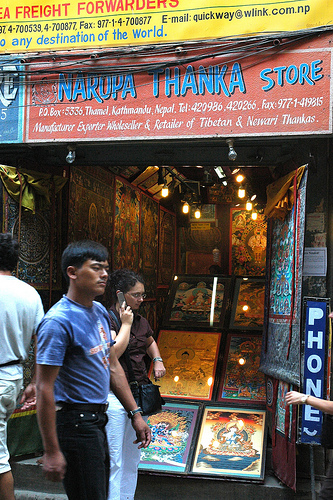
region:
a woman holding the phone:
[99, 268, 165, 392]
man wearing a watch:
[120, 399, 167, 447]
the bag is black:
[124, 370, 182, 431]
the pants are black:
[41, 390, 136, 497]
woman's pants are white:
[91, 386, 159, 496]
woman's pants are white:
[105, 382, 137, 496]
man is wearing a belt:
[75, 383, 104, 428]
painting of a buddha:
[197, 394, 275, 480]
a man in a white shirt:
[0, 233, 35, 499]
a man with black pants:
[43, 243, 113, 499]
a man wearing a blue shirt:
[42, 244, 111, 498]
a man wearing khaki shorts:
[0, 242, 39, 498]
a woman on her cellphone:
[110, 270, 147, 317]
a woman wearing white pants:
[110, 273, 144, 498]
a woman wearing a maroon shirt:
[111, 272, 159, 499]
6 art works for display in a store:
[161, 272, 270, 483]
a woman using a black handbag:
[111, 273, 162, 411]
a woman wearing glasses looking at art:
[112, 266, 148, 310]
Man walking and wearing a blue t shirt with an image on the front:
[23, 230, 125, 497]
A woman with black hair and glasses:
[110, 267, 169, 376]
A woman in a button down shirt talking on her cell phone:
[110, 275, 150, 356]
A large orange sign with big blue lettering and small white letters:
[26, 63, 329, 136]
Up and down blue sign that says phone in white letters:
[285, 285, 326, 462]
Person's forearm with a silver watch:
[282, 385, 330, 419]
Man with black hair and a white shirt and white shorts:
[0, 226, 29, 478]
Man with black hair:
[53, 232, 113, 310]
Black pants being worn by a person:
[29, 389, 119, 498]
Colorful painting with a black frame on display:
[190, 396, 272, 497]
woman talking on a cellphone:
[112, 261, 164, 377]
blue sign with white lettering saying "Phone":
[296, 297, 325, 453]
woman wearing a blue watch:
[152, 356, 164, 362]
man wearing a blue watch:
[125, 406, 142, 417]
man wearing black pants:
[56, 242, 116, 496]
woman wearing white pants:
[111, 270, 150, 498]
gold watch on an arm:
[299, 392, 310, 405]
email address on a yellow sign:
[161, 4, 312, 23]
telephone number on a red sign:
[177, 100, 259, 114]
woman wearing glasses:
[127, 288, 148, 298]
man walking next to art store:
[33, 235, 151, 499]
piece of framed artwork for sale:
[190, 400, 265, 480]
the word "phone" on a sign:
[299, 297, 330, 443]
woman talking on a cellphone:
[103, 265, 167, 499]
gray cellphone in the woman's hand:
[117, 291, 127, 311]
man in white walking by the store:
[0, 239, 45, 498]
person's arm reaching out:
[283, 389, 331, 412]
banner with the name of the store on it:
[23, 31, 330, 133]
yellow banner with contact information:
[0, 5, 331, 54]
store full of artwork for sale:
[3, 154, 300, 487]